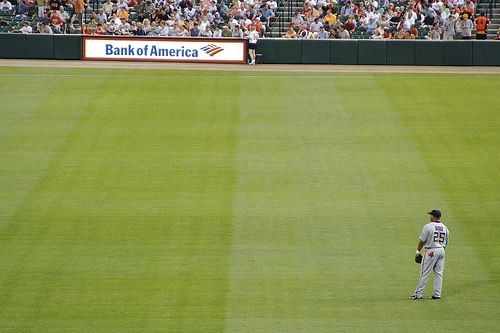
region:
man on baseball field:
[0, 2, 485, 327]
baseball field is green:
[46, 69, 377, 306]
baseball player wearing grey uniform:
[402, 209, 456, 293]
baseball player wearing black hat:
[422, 206, 448, 227]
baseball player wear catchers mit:
[408, 242, 428, 270]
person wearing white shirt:
[242, 28, 262, 42]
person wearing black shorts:
[245, 39, 259, 50]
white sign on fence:
[66, 18, 266, 79]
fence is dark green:
[0, 28, 498, 82]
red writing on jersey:
[419, 220, 451, 250]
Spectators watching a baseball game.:
[4, 4, 492, 41]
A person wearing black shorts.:
[245, 25, 260, 65]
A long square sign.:
[81, 31, 252, 63]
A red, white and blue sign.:
[78, 30, 249, 65]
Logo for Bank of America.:
[197, 37, 227, 59]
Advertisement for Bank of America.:
[77, 35, 247, 64]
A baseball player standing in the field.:
[408, 198, 460, 306]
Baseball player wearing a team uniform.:
[410, 196, 452, 306]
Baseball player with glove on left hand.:
[406, 198, 458, 307]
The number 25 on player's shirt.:
[429, 223, 446, 245]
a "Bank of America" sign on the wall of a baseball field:
[77, 34, 244, 66]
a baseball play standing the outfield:
[409, 209, 454, 302]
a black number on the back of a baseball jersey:
[431, 229, 446, 244]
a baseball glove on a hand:
[410, 247, 427, 267]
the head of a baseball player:
[425, 205, 445, 226]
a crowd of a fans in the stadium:
[292, 2, 485, 44]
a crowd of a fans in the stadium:
[90, 3, 259, 38]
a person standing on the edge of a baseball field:
[243, 19, 263, 69]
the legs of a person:
[245, 46, 259, 66]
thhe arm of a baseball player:
[410, 230, 428, 267]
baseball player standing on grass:
[412, 208, 447, 299]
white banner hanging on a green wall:
[82, 35, 247, 62]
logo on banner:
[201, 42, 223, 55]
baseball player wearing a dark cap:
[414, 209, 447, 298]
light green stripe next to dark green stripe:
[231, 73, 499, 331]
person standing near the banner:
[245, 25, 261, 64]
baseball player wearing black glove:
[412, 210, 452, 298]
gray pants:
[415, 246, 445, 295]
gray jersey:
[418, 223, 450, 248]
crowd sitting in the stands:
[283, 0, 490, 37]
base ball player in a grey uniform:
[404, 203, 460, 307]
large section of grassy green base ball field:
[0, 58, 498, 331]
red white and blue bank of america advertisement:
[77, 35, 247, 70]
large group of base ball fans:
[2, 5, 499, 39]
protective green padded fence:
[5, 30, 498, 75]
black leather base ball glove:
[413, 249, 421, 263]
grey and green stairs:
[257, 0, 309, 40]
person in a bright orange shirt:
[465, 10, 492, 42]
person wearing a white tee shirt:
[240, 18, 260, 64]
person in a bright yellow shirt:
[319, 4, 344, 26]